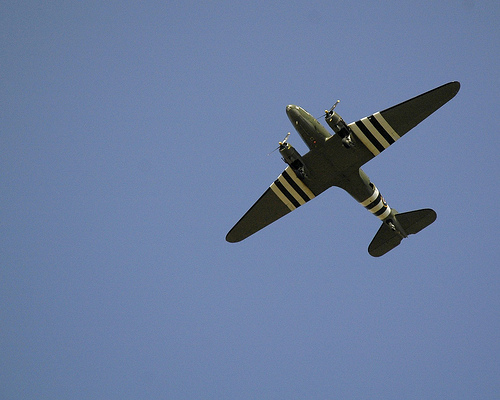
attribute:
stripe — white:
[370, 107, 400, 147]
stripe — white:
[355, 114, 391, 153]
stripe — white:
[346, 118, 381, 159]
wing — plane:
[344, 79, 462, 167]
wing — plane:
[225, 165, 331, 245]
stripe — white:
[284, 165, 315, 203]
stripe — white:
[274, 170, 305, 211]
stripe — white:
[268, 178, 297, 215]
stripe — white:
[355, 185, 382, 209]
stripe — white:
[368, 197, 385, 218]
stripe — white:
[372, 200, 392, 221]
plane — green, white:
[169, 74, 473, 262]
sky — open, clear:
[0, 2, 499, 399]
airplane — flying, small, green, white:
[220, 78, 463, 259]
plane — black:
[211, 76, 474, 258]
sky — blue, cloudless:
[10, 38, 260, 338]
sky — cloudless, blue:
[98, 262, 439, 390]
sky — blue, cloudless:
[87, 257, 371, 368]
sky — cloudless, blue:
[247, 267, 484, 378]